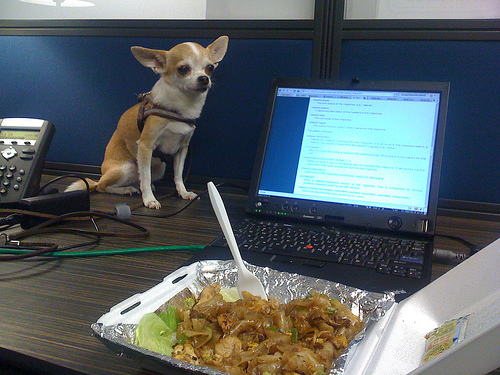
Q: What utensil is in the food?
A: A fork.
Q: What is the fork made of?
A: Plastic.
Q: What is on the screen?
A: A program.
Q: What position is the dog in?
A: Sitting.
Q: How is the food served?
A: In a container.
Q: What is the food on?
A: Tin foil.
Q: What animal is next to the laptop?
A: A chihuahua.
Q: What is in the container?
A: Food.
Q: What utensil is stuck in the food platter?
A: A fork.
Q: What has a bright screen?
A: The laptop.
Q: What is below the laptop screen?
A: The keyboard.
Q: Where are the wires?
A: On the desk.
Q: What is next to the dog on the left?
A: A telephone.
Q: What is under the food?
A: Aluminum foil.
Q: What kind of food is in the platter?
A: Meat.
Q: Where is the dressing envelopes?
A: On the lid of the platter.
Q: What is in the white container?
A: Food.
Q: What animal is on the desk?
A: Dog.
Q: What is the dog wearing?
A: Harness.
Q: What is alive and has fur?
A: Dog.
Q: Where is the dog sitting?
A: On the desk.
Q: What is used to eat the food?
A: A fork.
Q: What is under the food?
A: Foil.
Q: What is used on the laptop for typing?
A: Keyboard.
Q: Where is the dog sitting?
A: On desk.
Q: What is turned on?
A: Laptop screen.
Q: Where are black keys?
A: On the laptop.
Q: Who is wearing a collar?
A: Dog.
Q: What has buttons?
A: Telephone.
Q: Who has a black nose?
A: The dog.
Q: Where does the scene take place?
A: In an office.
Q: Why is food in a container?
A: To be eaten.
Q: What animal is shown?
A: Dog.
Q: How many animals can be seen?
A: 1.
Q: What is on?
A: Laptop.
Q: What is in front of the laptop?
A: Food.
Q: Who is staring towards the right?
A: Dog.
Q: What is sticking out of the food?
A: Fork.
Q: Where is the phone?
A: Left of the dog.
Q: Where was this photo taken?
A: At the office.